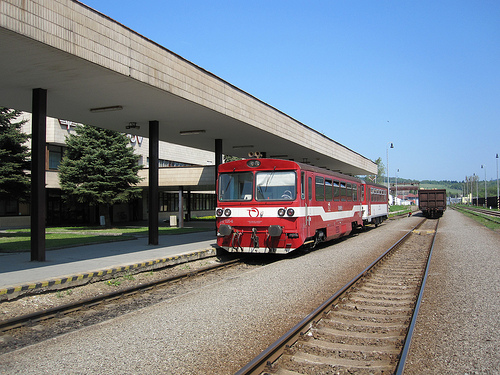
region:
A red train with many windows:
[217, 158, 390, 253]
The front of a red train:
[219, 158, 304, 254]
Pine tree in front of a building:
[62, 117, 142, 232]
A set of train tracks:
[247, 238, 440, 374]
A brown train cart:
[414, 187, 446, 221]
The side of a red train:
[301, 166, 363, 249]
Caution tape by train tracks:
[2, 246, 213, 286]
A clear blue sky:
[319, 3, 496, 103]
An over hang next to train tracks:
[2, 3, 182, 348]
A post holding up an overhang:
[27, 84, 49, 264]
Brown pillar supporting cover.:
[148, 119, 158, 244]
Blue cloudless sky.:
[293, 23, 474, 110]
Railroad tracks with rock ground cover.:
[234, 217, 445, 372]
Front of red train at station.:
[209, 159, 300, 256]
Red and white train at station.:
[213, 156, 388, 253]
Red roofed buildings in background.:
[390, 182, 417, 205]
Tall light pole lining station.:
[387, 142, 394, 207]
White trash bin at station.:
[170, 214, 177, 226]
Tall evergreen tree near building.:
[60, 122, 141, 222]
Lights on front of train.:
[216, 209, 293, 219]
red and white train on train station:
[207, 152, 394, 264]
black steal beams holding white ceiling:
[15, 72, 186, 267]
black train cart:
[415, 182, 457, 222]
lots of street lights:
[454, 152, 496, 204]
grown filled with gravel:
[450, 257, 497, 344]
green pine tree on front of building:
[55, 120, 142, 233]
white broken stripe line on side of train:
[308, 198, 372, 227]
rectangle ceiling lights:
[172, 122, 229, 147]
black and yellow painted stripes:
[16, 261, 180, 291]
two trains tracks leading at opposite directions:
[139, 224, 430, 366]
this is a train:
[220, 165, 356, 248]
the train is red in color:
[241, 169, 341, 248]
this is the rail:
[288, 290, 433, 352]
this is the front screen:
[257, 177, 293, 198]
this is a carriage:
[415, 188, 448, 212]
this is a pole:
[141, 112, 171, 247]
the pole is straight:
[139, 117, 169, 239]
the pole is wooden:
[144, 127, 171, 239]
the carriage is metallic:
[414, 185, 451, 215]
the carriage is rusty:
[417, 187, 447, 213]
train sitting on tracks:
[189, 140, 404, 272]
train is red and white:
[211, 149, 408, 274]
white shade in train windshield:
[256, 161, 316, 201]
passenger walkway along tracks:
[100, 59, 277, 271]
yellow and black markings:
[29, 250, 226, 280]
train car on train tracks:
[411, 177, 453, 252]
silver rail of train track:
[359, 251, 449, 374]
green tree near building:
[23, 132, 164, 220]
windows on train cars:
[298, 161, 430, 229]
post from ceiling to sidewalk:
[131, 30, 173, 262]